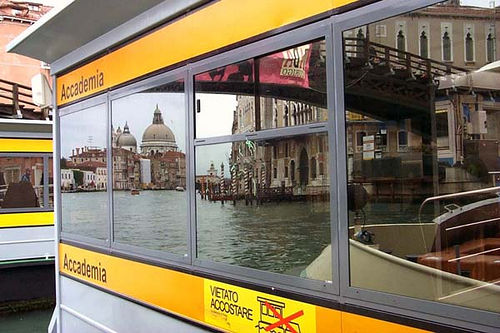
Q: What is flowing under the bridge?
A: Water.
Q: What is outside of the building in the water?
A: A large boat.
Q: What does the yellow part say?
A: Accademia.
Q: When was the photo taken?
A: Daytime.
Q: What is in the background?
A: A structure.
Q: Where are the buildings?
A: Reflected in the glass.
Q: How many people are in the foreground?
A: None.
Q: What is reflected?
A: Buildings.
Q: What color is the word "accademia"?
A: Yellow.